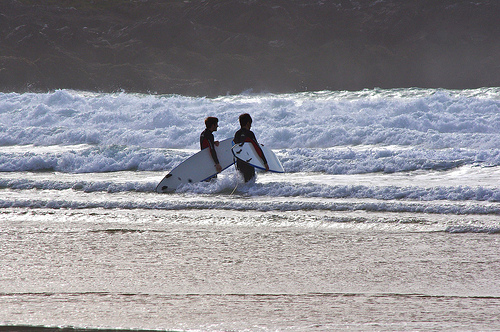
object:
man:
[230, 113, 269, 184]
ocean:
[0, 89, 497, 332]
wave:
[3, 140, 47, 167]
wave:
[57, 142, 125, 172]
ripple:
[5, 157, 25, 167]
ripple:
[9, 169, 19, 172]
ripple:
[44, 171, 64, 181]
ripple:
[79, 177, 95, 182]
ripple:
[79, 164, 90, 174]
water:
[3, 85, 494, 231]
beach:
[0, 221, 500, 330]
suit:
[232, 128, 267, 183]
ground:
[378, 162, 438, 219]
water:
[5, 224, 498, 329]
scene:
[0, 0, 495, 329]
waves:
[1, 87, 276, 117]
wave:
[392, 95, 474, 141]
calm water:
[0, 226, 499, 332]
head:
[239, 113, 253, 128]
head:
[205, 117, 220, 132]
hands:
[215, 164, 222, 174]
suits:
[199, 129, 219, 165]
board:
[230, 143, 286, 174]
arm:
[249, 136, 265, 159]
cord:
[229, 182, 240, 195]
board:
[154, 136, 245, 194]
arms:
[206, 137, 218, 162]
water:
[2, 88, 498, 215]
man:
[199, 117, 223, 182]